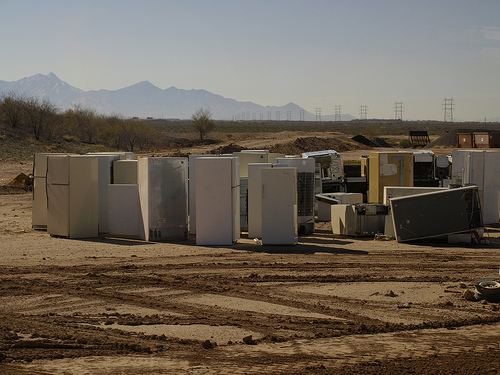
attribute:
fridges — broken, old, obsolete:
[26, 138, 499, 244]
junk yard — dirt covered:
[8, 129, 500, 370]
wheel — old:
[468, 277, 500, 299]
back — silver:
[388, 186, 479, 244]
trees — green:
[5, 93, 225, 154]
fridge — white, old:
[196, 157, 242, 245]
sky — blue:
[1, 0, 497, 121]